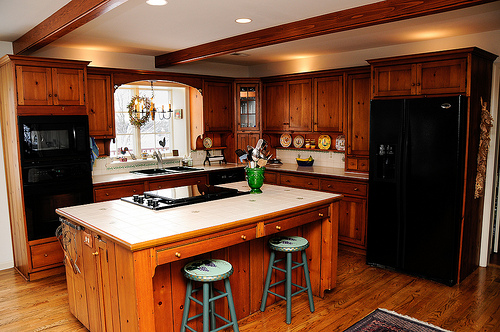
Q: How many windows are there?
A: One.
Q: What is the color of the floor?
A: Brown.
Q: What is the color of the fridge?
A: Black.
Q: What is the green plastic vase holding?
A: Utensils.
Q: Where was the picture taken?
A: Kitchen.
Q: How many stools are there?
A: Two.